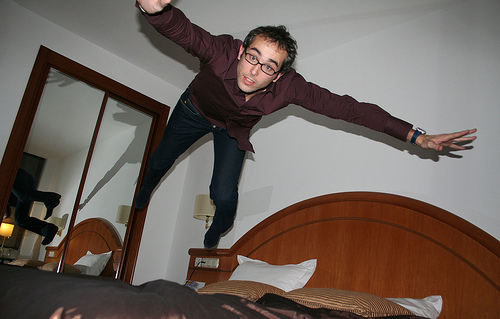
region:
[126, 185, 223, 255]
Man is wearing socks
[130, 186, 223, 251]
Man is wearing black socks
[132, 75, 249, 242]
Man is wearing pants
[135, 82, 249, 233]
Man is wearing jeans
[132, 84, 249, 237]
Man is wearing dark jeans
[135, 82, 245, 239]
Man is wearing blue jeans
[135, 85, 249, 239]
Man is wearing dark blue jeans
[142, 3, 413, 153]
Man is wearing a shirt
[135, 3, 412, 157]
Man is wearing a long sleeve shirt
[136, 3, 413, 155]
Man is wearing a dress shirt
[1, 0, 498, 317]
man is jumping onto bed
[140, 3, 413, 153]
man is wearing maroon shirt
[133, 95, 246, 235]
man is wearing dark blue jeans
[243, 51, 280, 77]
man wearing dark rimmed glasses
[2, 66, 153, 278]
mirror is on closet door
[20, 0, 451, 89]
man's shadow is on ceiling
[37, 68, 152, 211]
man's shadow is in mirror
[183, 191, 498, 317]
bed headboard is brown wood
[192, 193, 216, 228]
lamp is mounted on wall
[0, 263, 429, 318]
comforter on bed is brown and shiny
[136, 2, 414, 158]
Man is wearing a dark red shirt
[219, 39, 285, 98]
Man is wearing a collared shirt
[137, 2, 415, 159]
Man is wearing a dark red collared shirt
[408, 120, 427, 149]
Man is wearing a watch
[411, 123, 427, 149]
Man is wearing a black watch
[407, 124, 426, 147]
Man is wearing a wrist watch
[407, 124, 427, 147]
Man is wearing a black wrist watch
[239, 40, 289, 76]
Man is wearing glasses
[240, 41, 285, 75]
Man is wearing black glasses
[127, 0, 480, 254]
Man is in the air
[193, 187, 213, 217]
a beige lampshade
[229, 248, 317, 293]
a white pillow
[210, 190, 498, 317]
a brown headboard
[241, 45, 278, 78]
a man's eyeglasses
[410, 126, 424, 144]
a black wristwatch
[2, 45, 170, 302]
a large brown mirror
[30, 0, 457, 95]
part of a white ceiling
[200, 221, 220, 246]
a man's black dress sock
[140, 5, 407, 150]
a man's long sleeve maroon shirt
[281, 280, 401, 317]
a large brown pillow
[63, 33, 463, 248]
The man is jumping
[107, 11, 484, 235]
Pretending he is flying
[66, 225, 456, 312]
Jumping on the bed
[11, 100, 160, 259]
The mirror is reflective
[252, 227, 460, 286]
The headboard is wooden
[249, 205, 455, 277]
The headboard is brown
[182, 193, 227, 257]
Lamp on the table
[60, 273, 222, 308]
The sheets are dark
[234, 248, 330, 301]
The pillow is white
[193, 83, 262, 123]
His shirt is red